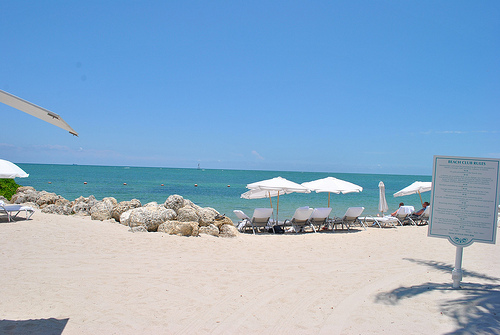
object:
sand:
[0, 200, 499, 334]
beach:
[0, 204, 499, 334]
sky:
[0, 1, 499, 176]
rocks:
[157, 220, 199, 238]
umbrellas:
[300, 175, 365, 195]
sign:
[425, 153, 500, 249]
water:
[0, 161, 432, 233]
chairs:
[307, 207, 334, 233]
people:
[410, 201, 430, 217]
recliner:
[240, 208, 275, 235]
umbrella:
[243, 172, 311, 192]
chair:
[271, 205, 316, 235]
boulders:
[127, 206, 179, 234]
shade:
[240, 224, 363, 235]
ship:
[195, 163, 203, 170]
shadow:
[374, 249, 500, 335]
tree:
[0, 177, 20, 202]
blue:
[1, 1, 499, 137]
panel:
[0, 89, 80, 136]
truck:
[0, 89, 78, 136]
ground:
[0, 203, 499, 333]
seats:
[330, 206, 367, 231]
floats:
[191, 181, 199, 188]